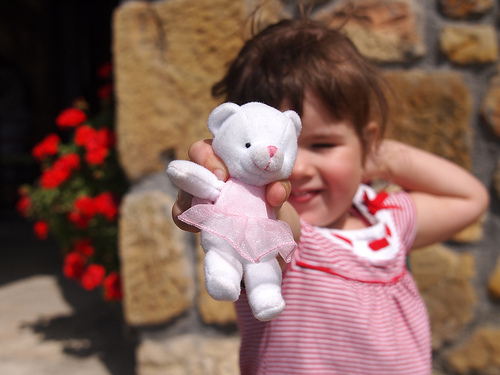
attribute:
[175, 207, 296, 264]
skirt — lace, pink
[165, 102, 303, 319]
teddy bear — white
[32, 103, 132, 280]
flowers — red, plant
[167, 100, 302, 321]
bear — white, small, pink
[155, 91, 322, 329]
bear — teddy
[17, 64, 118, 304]
flowers — red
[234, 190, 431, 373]
shirt — red and white, striped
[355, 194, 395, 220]
bow — red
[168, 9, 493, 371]
girl — red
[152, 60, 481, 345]
girl — little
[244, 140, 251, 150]
eye — small, black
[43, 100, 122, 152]
flower — red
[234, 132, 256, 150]
eye — little, black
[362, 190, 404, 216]
bow — red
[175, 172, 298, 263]
tutu — pink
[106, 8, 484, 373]
wall — stone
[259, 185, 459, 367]
dress — striped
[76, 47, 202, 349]
wall — stone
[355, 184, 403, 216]
bow — bright red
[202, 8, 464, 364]
girl — little